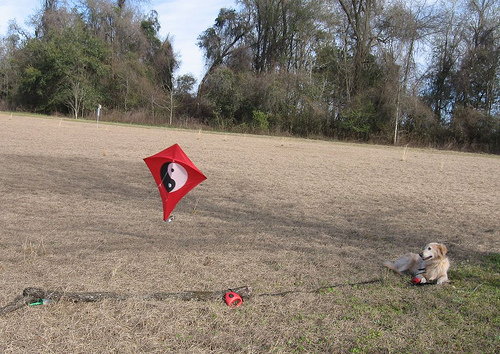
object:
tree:
[330, 0, 403, 142]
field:
[3, 98, 500, 354]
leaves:
[313, 94, 314, 95]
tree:
[35, 3, 108, 121]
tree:
[199, 56, 258, 129]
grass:
[0, 114, 498, 353]